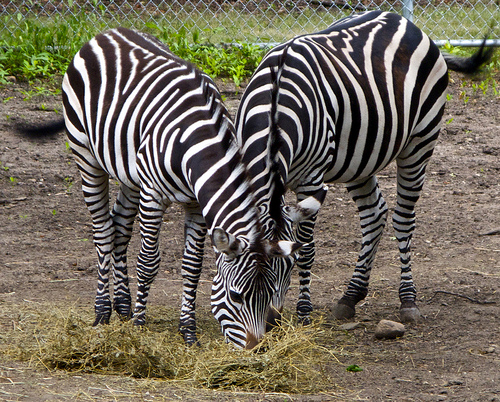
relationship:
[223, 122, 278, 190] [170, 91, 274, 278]
mane on top neck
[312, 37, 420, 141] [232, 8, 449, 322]
stripe fur on top of zebra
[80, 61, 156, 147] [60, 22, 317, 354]
stripe fur on top of zebra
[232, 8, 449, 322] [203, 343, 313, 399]
zebra grazing on grass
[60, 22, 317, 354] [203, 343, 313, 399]
zebra grazing on grass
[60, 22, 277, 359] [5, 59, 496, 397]
zebra standing on dirt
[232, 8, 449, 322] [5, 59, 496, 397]
zebra standing on dirt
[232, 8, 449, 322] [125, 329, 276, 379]
zebra eating hay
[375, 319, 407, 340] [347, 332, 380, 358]
brown rock on ground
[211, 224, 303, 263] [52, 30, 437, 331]
ears on zebra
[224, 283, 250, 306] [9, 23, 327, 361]
eye on zebra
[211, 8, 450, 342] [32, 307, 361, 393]
zebra eating hay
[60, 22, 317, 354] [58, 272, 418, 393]
zebra standing on dirt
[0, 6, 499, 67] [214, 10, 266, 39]
grass growing behind fence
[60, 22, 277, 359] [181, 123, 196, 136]
zebra has stripes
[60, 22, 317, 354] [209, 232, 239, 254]
zebra has ear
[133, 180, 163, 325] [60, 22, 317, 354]
leg on zebra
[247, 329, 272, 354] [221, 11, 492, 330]
nose of zebra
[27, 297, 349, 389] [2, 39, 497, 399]
hay on ground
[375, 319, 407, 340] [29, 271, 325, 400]
brown rock on ground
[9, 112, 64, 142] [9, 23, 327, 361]
tail on zebra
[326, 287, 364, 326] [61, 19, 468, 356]
hoof of zebra